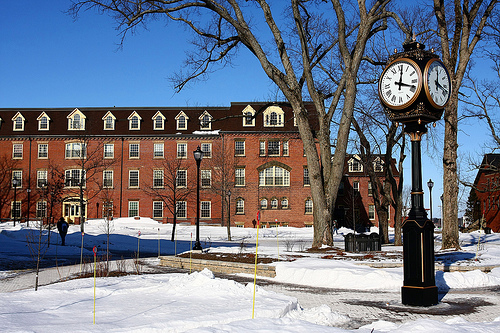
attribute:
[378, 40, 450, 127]
clock — large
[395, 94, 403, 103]
numeral — roman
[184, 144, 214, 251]
pole — tall , black 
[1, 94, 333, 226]
building — brown , short 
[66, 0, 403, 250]
tree — large, leafless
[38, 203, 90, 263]
person — background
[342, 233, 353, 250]
trashcan — black 